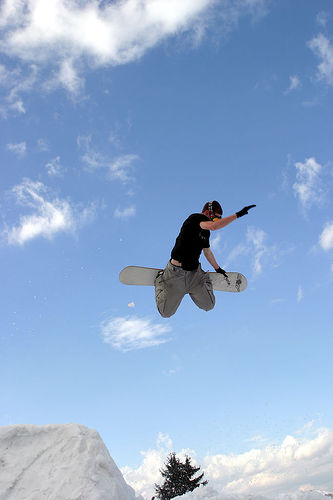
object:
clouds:
[26, 3, 151, 51]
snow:
[8, 429, 94, 494]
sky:
[54, 365, 305, 416]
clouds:
[235, 448, 330, 483]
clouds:
[142, 3, 189, 42]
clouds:
[9, 194, 78, 241]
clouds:
[319, 21, 331, 77]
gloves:
[214, 266, 229, 278]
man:
[153, 197, 254, 318]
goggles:
[204, 201, 222, 219]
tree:
[154, 451, 204, 498]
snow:
[140, 470, 330, 498]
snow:
[3, 425, 124, 498]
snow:
[2, 428, 139, 497]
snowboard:
[117, 263, 249, 294]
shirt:
[168, 213, 211, 265]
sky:
[3, 7, 328, 191]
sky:
[7, 316, 331, 423]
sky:
[168, 329, 332, 460]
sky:
[211, 409, 329, 494]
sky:
[168, 18, 329, 196]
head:
[204, 197, 223, 219]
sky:
[21, 65, 303, 436]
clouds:
[100, 309, 166, 353]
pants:
[153, 260, 215, 317]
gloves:
[236, 203, 252, 220]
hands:
[237, 203, 255, 218]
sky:
[17, 50, 317, 302]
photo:
[10, 7, 332, 465]